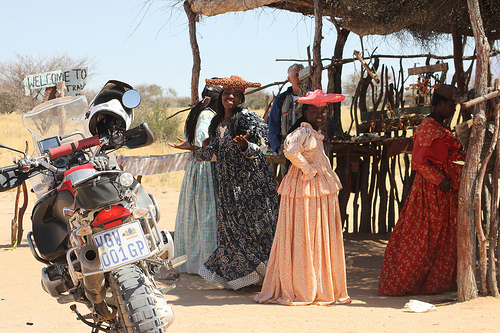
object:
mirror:
[122, 90, 141, 108]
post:
[453, 2, 490, 299]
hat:
[205, 75, 262, 91]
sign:
[23, 68, 88, 97]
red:
[101, 207, 120, 224]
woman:
[168, 75, 277, 290]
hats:
[298, 89, 346, 107]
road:
[0, 104, 500, 331]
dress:
[190, 107, 278, 290]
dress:
[172, 107, 219, 283]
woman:
[253, 89, 350, 305]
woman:
[375, 84, 464, 297]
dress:
[252, 121, 349, 305]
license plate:
[90, 220, 152, 272]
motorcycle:
[0, 81, 190, 332]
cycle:
[0, 80, 174, 333]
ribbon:
[202, 96, 211, 103]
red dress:
[378, 117, 467, 297]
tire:
[108, 263, 174, 332]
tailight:
[91, 205, 131, 228]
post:
[55, 78, 67, 137]